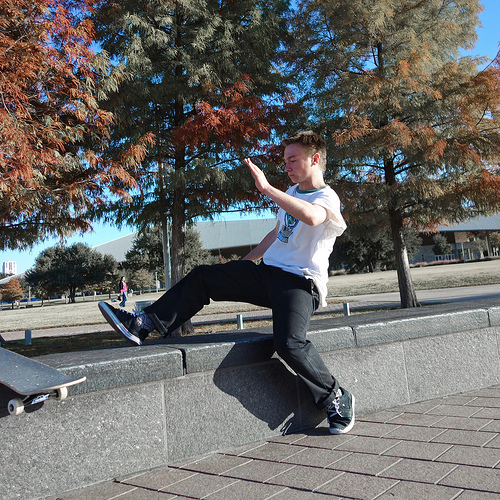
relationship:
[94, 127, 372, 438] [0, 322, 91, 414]
man doing skateboard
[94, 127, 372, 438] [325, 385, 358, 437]
man wearing shoe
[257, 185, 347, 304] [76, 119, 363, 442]
shirt on man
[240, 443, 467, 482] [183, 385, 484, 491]
pavers on sidewalk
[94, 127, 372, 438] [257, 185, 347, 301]
man wearing shirt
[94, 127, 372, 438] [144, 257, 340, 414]
man wearing pant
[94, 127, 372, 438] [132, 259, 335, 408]
man wearing jeans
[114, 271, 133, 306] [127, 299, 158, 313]
someone on sidewalk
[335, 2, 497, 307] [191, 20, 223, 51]
trees has leaves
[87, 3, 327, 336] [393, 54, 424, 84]
tree has leaves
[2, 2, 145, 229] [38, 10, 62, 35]
tree has leaves